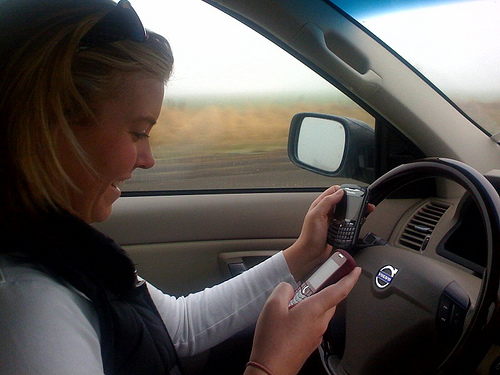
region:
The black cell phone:
[323, 175, 369, 255]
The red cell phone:
[285, 242, 355, 302]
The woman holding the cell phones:
[0, 0, 375, 370]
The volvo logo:
[370, 255, 400, 292]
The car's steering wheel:
[302, 145, 497, 370]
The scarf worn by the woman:
[0, 180, 185, 370]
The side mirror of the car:
[287, 105, 372, 175]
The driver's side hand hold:
[295, 20, 381, 95]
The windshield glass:
[327, 0, 497, 146]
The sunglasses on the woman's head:
[70, 0, 150, 57]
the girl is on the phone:
[219, 245, 369, 363]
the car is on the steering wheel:
[351, 253, 465, 361]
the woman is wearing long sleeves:
[156, 278, 242, 361]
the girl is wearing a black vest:
[10, 215, 157, 372]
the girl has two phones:
[294, 198, 366, 361]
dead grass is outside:
[182, 92, 374, 204]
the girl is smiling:
[42, 62, 158, 219]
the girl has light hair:
[30, 58, 102, 235]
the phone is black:
[332, 172, 430, 351]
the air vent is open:
[387, 194, 474, 289]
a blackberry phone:
[332, 183, 363, 243]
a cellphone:
[298, 248, 349, 288]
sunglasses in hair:
[117, 2, 154, 39]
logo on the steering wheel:
[369, 261, 401, 291]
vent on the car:
[419, 201, 440, 225]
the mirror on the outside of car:
[290, 116, 349, 169]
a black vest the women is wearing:
[107, 297, 172, 363]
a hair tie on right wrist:
[251, 353, 265, 370]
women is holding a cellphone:
[324, 190, 371, 250]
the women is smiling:
[110, 163, 135, 205]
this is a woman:
[9, 15, 382, 370]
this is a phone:
[266, 246, 377, 327]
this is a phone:
[311, 169, 375, 267]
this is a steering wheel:
[296, 150, 498, 371]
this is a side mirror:
[276, 100, 369, 186]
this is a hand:
[104, 178, 365, 322]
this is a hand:
[239, 274, 367, 374]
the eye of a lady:
[126, 112, 153, 154]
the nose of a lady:
[138, 146, 158, 188]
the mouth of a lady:
[106, 172, 143, 212]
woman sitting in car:
[20, 11, 487, 371]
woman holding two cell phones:
[6, 3, 388, 362]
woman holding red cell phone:
[249, 246, 367, 357]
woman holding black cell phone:
[297, 177, 387, 255]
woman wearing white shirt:
[14, 194, 301, 373]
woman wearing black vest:
[15, 192, 210, 370]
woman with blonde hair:
[0, 10, 197, 233]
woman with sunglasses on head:
[61, 0, 174, 76]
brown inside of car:
[138, 182, 469, 364]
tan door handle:
[274, 9, 415, 126]